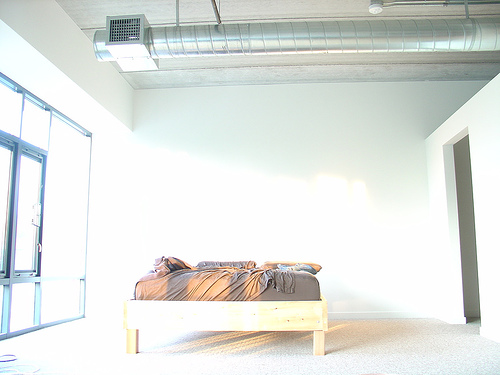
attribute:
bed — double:
[132, 254, 325, 300]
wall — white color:
[90, 79, 479, 321]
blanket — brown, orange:
[133, 254, 323, 301]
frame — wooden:
[91, 281, 386, 371]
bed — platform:
[83, 221, 436, 372]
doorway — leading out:
[419, 118, 485, 298]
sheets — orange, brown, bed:
[108, 242, 357, 326]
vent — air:
[79, 9, 433, 99]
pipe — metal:
[116, 10, 485, 87]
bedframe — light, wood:
[116, 290, 389, 360]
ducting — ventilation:
[149, 15, 469, 93]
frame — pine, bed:
[111, 226, 384, 364]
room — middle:
[43, 76, 484, 336]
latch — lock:
[18, 206, 58, 269]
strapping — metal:
[165, 5, 327, 63]